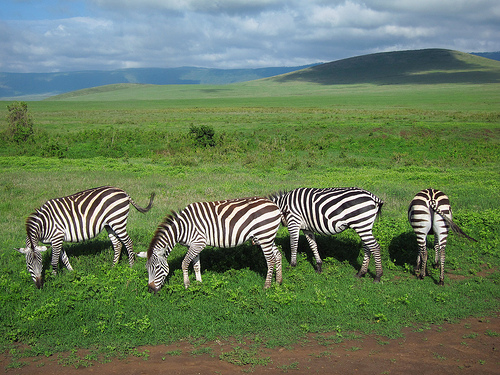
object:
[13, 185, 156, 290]
zebra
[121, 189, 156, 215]
tail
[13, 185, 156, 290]
stripes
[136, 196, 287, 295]
zebra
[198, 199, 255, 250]
stripes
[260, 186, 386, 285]
zebra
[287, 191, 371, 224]
stripes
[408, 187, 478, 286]
zebra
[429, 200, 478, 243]
tail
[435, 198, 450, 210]
stripes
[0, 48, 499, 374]
grass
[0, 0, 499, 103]
sky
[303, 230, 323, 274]
leg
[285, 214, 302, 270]
leg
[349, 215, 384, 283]
leg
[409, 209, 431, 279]
leg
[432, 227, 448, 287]
leg